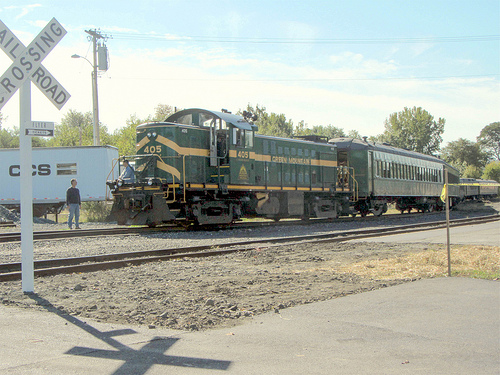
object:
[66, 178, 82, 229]
man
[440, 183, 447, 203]
flag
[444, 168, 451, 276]
stick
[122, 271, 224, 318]
rocks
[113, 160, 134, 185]
driver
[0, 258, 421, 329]
dirt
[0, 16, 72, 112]
sign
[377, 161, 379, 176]
window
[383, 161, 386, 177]
window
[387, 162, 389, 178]
window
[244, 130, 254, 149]
window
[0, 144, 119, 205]
trailer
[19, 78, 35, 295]
pole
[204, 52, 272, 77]
clouds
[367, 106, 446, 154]
bush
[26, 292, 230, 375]
shadow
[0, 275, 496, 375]
ground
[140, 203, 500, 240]
shadow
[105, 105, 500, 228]
green train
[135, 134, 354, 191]
yellow stripes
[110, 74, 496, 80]
wire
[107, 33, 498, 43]
wire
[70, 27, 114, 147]
pole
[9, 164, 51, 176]
ccs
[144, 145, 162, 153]
number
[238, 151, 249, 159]
number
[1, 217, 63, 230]
dirt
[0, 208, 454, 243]
track